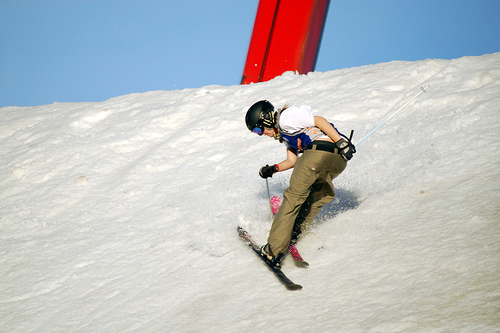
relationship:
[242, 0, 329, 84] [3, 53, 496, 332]
object on top of snow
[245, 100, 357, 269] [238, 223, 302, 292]
man wearing ski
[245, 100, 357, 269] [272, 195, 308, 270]
man wearing ski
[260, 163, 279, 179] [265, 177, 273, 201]
hand carrying stick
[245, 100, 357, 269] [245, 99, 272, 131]
man wearing helmet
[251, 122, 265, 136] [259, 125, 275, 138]
surfing goggles on face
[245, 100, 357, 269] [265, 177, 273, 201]
man holding stick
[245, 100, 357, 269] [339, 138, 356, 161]
man has glove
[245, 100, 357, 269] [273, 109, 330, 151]
man wearing shirt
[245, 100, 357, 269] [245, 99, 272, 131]
man wering helmet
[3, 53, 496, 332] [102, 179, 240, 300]
snow on ground